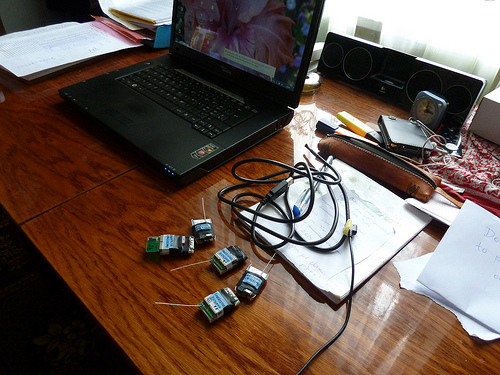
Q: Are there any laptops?
A: Yes, there is a laptop.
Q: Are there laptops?
A: Yes, there is a laptop.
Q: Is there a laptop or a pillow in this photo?
A: Yes, there is a laptop.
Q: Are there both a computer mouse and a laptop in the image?
A: No, there is a laptop but no computer mice.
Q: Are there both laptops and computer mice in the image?
A: No, there is a laptop but no computer mice.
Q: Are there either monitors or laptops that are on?
A: Yes, the laptop is on.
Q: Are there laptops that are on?
A: Yes, there is a laptop that is on.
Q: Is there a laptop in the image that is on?
A: Yes, there is a laptop that is on.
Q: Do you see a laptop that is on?
A: Yes, there is a laptop that is on.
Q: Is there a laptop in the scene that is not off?
A: Yes, there is a laptop that is on.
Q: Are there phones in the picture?
A: No, there are no phones.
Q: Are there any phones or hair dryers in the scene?
A: No, there are no phones or hair dryers.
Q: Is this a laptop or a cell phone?
A: This is a laptop.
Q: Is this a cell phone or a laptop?
A: This is a laptop.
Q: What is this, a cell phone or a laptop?
A: This is a laptop.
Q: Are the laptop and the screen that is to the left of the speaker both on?
A: Yes, both the laptop and the screen are on.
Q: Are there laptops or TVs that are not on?
A: No, there is a laptop but it is on.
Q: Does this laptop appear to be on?
A: Yes, the laptop is on.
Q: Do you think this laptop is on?
A: Yes, the laptop is on.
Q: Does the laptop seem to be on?
A: Yes, the laptop is on.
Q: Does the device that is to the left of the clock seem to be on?
A: Yes, the laptop is on.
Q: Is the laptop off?
A: No, the laptop is on.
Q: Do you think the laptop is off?
A: No, the laptop is on.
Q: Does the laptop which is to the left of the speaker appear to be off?
A: No, the laptop is on.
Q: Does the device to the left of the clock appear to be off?
A: No, the laptop is on.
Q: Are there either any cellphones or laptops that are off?
A: No, there is a laptop but it is on.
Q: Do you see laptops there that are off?
A: No, there is a laptop but it is on.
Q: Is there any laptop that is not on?
A: No, there is a laptop but it is on.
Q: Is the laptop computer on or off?
A: The laptop computer is on.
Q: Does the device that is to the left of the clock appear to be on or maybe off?
A: The laptop computer is on.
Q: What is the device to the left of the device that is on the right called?
A: The device is a laptop.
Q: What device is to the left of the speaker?
A: The device is a laptop.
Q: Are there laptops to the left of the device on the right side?
A: Yes, there is a laptop to the left of the speaker.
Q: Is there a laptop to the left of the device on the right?
A: Yes, there is a laptop to the left of the speaker.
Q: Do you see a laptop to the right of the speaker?
A: No, the laptop is to the left of the speaker.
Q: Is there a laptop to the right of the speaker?
A: No, the laptop is to the left of the speaker.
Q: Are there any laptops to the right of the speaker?
A: No, the laptop is to the left of the speaker.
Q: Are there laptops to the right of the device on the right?
A: No, the laptop is to the left of the speaker.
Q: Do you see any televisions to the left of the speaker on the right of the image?
A: No, there is a laptop to the left of the speaker.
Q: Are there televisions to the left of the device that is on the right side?
A: No, there is a laptop to the left of the speaker.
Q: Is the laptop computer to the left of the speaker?
A: Yes, the laptop computer is to the left of the speaker.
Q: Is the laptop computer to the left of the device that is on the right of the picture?
A: Yes, the laptop computer is to the left of the speaker.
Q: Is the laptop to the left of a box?
A: No, the laptop is to the left of the speaker.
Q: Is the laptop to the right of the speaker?
A: No, the laptop is to the left of the speaker.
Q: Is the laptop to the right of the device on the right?
A: No, the laptop is to the left of the speaker.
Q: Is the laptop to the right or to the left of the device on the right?
A: The laptop is to the left of the speaker.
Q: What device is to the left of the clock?
A: The device is a laptop.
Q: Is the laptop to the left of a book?
A: No, the laptop is to the left of the clock.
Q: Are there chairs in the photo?
A: No, there are no chairs.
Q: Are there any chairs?
A: No, there are no chairs.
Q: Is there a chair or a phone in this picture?
A: No, there are no chairs or phones.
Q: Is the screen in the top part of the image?
A: Yes, the screen is in the top of the image.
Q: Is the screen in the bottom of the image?
A: No, the screen is in the top of the image.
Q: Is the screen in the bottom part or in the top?
A: The screen is in the top of the image.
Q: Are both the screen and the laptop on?
A: Yes, both the screen and the laptop are on.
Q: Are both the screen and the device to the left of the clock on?
A: Yes, both the screen and the laptop are on.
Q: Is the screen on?
A: Yes, the screen is on.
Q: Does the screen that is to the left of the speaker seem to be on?
A: Yes, the screen is on.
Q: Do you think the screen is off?
A: No, the screen is on.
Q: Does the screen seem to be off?
A: No, the screen is on.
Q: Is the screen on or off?
A: The screen is on.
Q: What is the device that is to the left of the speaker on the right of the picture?
A: The device is a screen.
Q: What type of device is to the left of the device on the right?
A: The device is a screen.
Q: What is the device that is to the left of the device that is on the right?
A: The device is a screen.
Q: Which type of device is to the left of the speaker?
A: The device is a screen.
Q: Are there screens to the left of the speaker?
A: Yes, there is a screen to the left of the speaker.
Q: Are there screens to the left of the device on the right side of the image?
A: Yes, there is a screen to the left of the speaker.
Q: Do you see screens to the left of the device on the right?
A: Yes, there is a screen to the left of the speaker.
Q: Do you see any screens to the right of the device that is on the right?
A: No, the screen is to the left of the speaker.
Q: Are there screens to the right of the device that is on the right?
A: No, the screen is to the left of the speaker.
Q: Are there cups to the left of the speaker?
A: No, there is a screen to the left of the speaker.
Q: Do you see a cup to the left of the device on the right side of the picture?
A: No, there is a screen to the left of the speaker.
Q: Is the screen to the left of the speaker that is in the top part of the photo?
A: Yes, the screen is to the left of the speaker.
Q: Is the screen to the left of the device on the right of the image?
A: Yes, the screen is to the left of the speaker.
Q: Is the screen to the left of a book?
A: No, the screen is to the left of the speaker.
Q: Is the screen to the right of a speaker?
A: No, the screen is to the left of a speaker.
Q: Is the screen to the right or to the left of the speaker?
A: The screen is to the left of the speaker.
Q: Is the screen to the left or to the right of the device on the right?
A: The screen is to the left of the speaker.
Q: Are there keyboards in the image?
A: Yes, there is a keyboard.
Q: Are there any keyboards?
A: Yes, there is a keyboard.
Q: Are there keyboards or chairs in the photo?
A: Yes, there is a keyboard.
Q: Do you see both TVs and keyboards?
A: No, there is a keyboard but no televisions.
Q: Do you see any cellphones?
A: No, there are no cellphones.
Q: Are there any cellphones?
A: No, there are no cellphones.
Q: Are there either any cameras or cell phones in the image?
A: No, there are no cell phones or cameras.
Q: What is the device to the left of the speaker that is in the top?
A: The device is a keyboard.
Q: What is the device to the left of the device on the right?
A: The device is a keyboard.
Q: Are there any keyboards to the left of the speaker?
A: Yes, there is a keyboard to the left of the speaker.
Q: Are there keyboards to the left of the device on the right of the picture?
A: Yes, there is a keyboard to the left of the speaker.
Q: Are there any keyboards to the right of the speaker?
A: No, the keyboard is to the left of the speaker.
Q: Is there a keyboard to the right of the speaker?
A: No, the keyboard is to the left of the speaker.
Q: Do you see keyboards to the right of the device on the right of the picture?
A: No, the keyboard is to the left of the speaker.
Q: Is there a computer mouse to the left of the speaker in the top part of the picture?
A: No, there is a keyboard to the left of the speaker.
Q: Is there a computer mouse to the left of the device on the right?
A: No, there is a keyboard to the left of the speaker.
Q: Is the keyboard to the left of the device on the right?
A: Yes, the keyboard is to the left of the speaker.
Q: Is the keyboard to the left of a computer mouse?
A: No, the keyboard is to the left of the speaker.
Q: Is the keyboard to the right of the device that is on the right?
A: No, the keyboard is to the left of the speaker.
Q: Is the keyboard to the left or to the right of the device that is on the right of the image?
A: The keyboard is to the left of the speaker.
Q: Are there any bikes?
A: No, there are no bikes.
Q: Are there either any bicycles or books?
A: No, there are no bicycles or books.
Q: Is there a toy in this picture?
A: No, there are no toys.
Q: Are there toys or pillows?
A: No, there are no toys or pillows.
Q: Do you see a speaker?
A: Yes, there is a speaker.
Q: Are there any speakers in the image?
A: Yes, there is a speaker.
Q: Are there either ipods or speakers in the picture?
A: Yes, there is a speaker.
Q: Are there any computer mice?
A: No, there are no computer mice.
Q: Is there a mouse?
A: No, there are no computer mice.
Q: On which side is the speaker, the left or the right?
A: The speaker is on the right of the image.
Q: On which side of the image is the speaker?
A: The speaker is on the right of the image.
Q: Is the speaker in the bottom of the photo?
A: No, the speaker is in the top of the image.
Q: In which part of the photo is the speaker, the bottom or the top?
A: The speaker is in the top of the image.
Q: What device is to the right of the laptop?
A: The device is a speaker.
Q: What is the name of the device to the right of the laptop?
A: The device is a speaker.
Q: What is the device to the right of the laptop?
A: The device is a speaker.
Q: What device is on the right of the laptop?
A: The device is a speaker.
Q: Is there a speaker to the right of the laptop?
A: Yes, there is a speaker to the right of the laptop.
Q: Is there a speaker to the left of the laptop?
A: No, the speaker is to the right of the laptop.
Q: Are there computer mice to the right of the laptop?
A: No, there is a speaker to the right of the laptop.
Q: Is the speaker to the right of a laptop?
A: Yes, the speaker is to the right of a laptop.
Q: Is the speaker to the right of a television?
A: No, the speaker is to the right of a laptop.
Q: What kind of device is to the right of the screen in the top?
A: The device is a speaker.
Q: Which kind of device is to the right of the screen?
A: The device is a speaker.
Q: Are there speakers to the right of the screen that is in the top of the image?
A: Yes, there is a speaker to the right of the screen.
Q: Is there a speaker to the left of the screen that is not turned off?
A: No, the speaker is to the right of the screen.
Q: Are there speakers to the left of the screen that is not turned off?
A: No, the speaker is to the right of the screen.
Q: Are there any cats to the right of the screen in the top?
A: No, there is a speaker to the right of the screen.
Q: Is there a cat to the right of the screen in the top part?
A: No, there is a speaker to the right of the screen.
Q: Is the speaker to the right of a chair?
A: No, the speaker is to the right of a screen.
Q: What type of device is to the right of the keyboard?
A: The device is a speaker.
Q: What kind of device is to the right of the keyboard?
A: The device is a speaker.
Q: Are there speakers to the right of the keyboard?
A: Yes, there is a speaker to the right of the keyboard.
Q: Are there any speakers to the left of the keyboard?
A: No, the speaker is to the right of the keyboard.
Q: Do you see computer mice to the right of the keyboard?
A: No, there is a speaker to the right of the keyboard.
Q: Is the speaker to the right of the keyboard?
A: Yes, the speaker is to the right of the keyboard.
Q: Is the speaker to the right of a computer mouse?
A: No, the speaker is to the right of the keyboard.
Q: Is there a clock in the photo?
A: Yes, there is a clock.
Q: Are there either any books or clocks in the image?
A: Yes, there is a clock.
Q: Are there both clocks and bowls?
A: No, there is a clock but no bowls.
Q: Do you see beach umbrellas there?
A: No, there are no beach umbrellas.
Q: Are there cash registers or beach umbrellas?
A: No, there are no beach umbrellas or cash registers.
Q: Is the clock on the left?
A: No, the clock is on the right of the image.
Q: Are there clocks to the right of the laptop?
A: Yes, there is a clock to the right of the laptop.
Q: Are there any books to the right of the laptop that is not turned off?
A: No, there is a clock to the right of the laptop.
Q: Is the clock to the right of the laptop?
A: Yes, the clock is to the right of the laptop.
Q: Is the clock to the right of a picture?
A: No, the clock is to the right of the laptop.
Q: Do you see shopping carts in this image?
A: No, there are no shopping carts.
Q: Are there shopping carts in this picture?
A: No, there are no shopping carts.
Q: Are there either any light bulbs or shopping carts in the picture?
A: No, there are no shopping carts or light bulbs.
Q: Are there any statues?
A: No, there are no statues.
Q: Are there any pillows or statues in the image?
A: No, there are no statues or pillows.